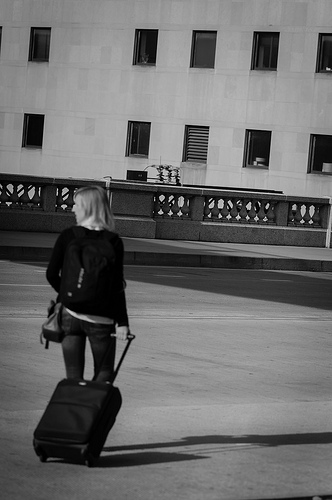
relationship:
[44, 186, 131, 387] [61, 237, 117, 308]
woman wearing backpack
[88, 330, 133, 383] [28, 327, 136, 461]
handle on suitcase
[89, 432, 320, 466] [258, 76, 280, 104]
shadow on ground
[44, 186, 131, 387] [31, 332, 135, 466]
woman pulling suitcase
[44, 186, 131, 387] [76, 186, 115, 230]
woman has blonde hair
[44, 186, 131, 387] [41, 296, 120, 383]
woman wearing jeans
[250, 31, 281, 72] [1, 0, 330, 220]
blinds on building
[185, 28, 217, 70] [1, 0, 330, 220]
building window on building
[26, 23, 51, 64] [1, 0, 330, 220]
building window on building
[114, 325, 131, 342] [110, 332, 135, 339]
hand holding luggage handle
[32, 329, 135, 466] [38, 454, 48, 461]
bag on wheel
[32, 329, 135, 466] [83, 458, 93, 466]
bag on wheel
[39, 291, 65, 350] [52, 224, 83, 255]
bag hanging from shoulder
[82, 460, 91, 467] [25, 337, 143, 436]
wheel on luggage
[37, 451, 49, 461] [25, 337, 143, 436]
wheel on luggage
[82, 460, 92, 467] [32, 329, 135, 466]
wheel on bag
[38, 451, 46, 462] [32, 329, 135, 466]
wheel on bag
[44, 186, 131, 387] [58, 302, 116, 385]
woman wearing jeans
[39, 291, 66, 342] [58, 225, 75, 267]
bag on shoulder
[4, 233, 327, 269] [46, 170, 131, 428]
sidewalk across from woman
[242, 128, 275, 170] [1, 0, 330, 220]
window on building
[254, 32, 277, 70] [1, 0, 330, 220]
window on building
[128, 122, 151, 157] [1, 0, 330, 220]
window on building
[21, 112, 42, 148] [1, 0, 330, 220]
window on building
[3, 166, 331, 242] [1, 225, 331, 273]
decorative wall near sidewalk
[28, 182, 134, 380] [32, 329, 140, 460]
woman holding bag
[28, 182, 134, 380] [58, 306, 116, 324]
woman wearing shirt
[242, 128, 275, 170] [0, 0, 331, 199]
window on building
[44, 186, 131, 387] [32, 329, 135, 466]
woman pulling bag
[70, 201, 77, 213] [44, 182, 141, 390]
nose on face woman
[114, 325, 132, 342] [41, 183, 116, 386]
hand attached to woman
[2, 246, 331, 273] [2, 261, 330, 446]
curb next to street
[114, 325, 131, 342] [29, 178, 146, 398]
hand attached to woman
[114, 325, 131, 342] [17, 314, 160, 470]
hand holding luggage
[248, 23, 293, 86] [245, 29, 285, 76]
blinds on window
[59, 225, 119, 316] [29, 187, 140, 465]
back belonging to woman